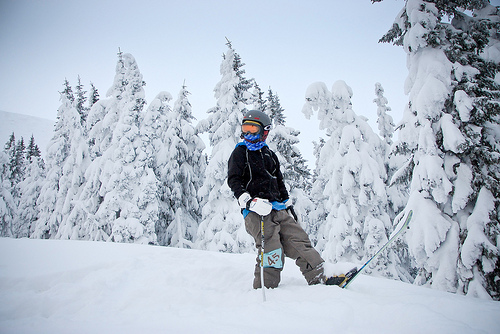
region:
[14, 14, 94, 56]
The sky is clear.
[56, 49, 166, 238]
The trees in the background are covered in snow.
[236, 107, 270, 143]
The person is wearing ski goggles.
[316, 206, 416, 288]
One ski up in the air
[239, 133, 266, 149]
Blue and white scarf around man's neck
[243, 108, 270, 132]
Gray hat on man's head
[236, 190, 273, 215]
White ski glove on man's hand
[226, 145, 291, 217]
Men's black ski jacket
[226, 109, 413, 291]
Man standing still in snow looking to the side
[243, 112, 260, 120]
Red lettering on top of man's hat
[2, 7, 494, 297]
branches of pine trees covered with snow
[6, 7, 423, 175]
blue sky and mountain curve behind trees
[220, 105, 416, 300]
skier with legs partially in snow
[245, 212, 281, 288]
number on patch on leg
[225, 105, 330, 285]
helmeted skier looking backwards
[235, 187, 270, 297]
long white mitten holding pole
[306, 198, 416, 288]
ski slanted upward from snow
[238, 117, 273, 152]
skier wearing bright blue scarf around neck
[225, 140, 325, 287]
skier wearing black jacket over gray pants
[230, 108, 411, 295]
person is snowboarding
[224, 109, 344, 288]
person is wearing gray helmet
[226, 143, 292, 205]
person is wearing black jacket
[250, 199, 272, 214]
person is wearing white mittens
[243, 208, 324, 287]
person is wearing gray pants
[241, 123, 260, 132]
person is wearing snow goggles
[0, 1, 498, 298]
snow is on trees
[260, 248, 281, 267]
blue patch with the number 45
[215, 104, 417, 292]
a man on a snowboard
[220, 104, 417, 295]
a man in gray pants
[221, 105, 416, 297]
an athlete in orange glasses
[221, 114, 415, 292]
a man wearing a blue scarf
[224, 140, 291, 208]
black jacket on the skier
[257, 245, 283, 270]
number on the pants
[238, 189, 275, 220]
white glove on the hand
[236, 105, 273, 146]
helmet on the person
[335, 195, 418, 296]
ski on the foot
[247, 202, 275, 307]
ski pole in the hand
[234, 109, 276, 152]
goggles on the person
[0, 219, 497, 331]
snow covering the ground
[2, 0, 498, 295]
snow covered trees beside the man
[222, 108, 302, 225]
black jacket on the person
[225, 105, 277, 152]
blue scarf on the person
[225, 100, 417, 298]
A skier in deep snow.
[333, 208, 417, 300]
One ski lifted in the air.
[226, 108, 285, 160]
A blue scarf around the skier's neck.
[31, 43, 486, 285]
Snow covers the pine trees.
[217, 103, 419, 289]
The skier has a grey helmet on.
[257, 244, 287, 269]
A number 45 on the skier's leg.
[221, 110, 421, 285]
A person wearing skis.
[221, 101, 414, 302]
The skier holds a ski pole.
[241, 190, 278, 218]
The person wears a white glove.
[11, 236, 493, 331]
A snow covered area.